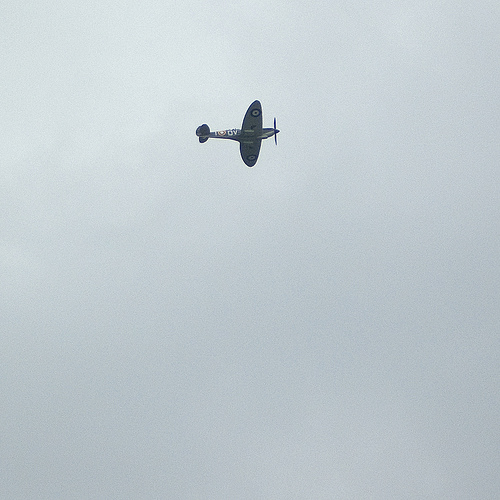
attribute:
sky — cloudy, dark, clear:
[3, 3, 499, 497]